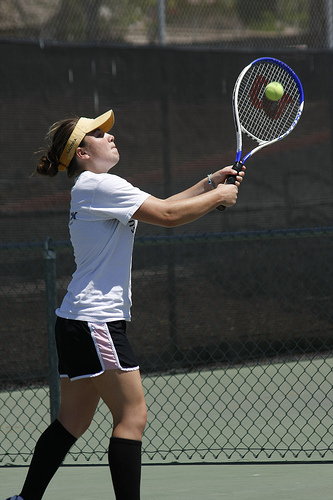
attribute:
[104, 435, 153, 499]
sock — is black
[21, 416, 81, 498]
sock — is black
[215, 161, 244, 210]
handle — black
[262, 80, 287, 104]
yellow ball — is yellow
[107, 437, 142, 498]
black socks — are black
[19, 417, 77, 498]
black socks — are black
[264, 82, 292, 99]
tennis ball — yellow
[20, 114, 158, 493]
woman — is white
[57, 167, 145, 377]
dress — is black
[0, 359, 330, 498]
ground — are grey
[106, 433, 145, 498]
socks — black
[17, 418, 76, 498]
socks — black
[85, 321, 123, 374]
strip — is pink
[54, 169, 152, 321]
shirt — white